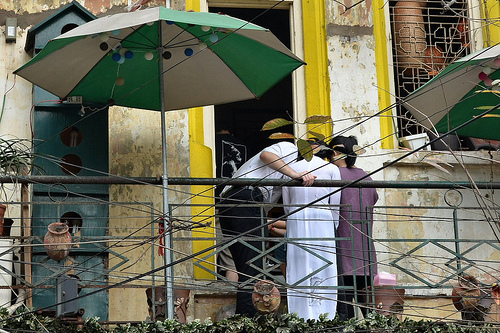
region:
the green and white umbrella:
[10, 5, 306, 114]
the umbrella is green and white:
[11, 7, 309, 115]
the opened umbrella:
[12, 4, 307, 114]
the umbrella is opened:
[10, 6, 307, 114]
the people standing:
[223, 129, 378, 315]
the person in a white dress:
[287, 148, 334, 323]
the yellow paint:
[309, 25, 324, 117]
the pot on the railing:
[46, 217, 67, 261]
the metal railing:
[29, 161, 495, 318]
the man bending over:
[217, 137, 291, 299]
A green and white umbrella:
[67, 26, 230, 91]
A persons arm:
[263, 158, 309, 183]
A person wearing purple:
[341, 168, 380, 234]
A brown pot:
[48, 225, 79, 252]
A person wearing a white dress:
[283, 166, 334, 270]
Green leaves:
[236, 311, 341, 328]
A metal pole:
[153, 112, 174, 194]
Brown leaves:
[263, 120, 307, 142]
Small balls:
[115, 50, 176, 64]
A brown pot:
[233, 277, 283, 311]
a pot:
[232, 281, 310, 325]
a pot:
[231, 264, 283, 316]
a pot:
[234, 250, 299, 330]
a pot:
[238, 280, 295, 307]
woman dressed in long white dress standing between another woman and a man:
[284, 143, 341, 312]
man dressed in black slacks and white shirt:
[216, 136, 324, 313]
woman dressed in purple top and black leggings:
[325, 127, 387, 312]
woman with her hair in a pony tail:
[326, 130, 385, 312]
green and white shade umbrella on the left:
[14, 3, 306, 330]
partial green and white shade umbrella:
[405, 32, 498, 147]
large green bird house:
[14, 12, 122, 310]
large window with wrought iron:
[382, 0, 487, 147]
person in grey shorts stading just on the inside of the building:
[212, 199, 239, 284]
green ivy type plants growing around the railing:
[3, 308, 488, 330]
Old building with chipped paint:
[3, 5, 494, 289]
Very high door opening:
[180, 2, 345, 289]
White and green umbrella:
[21, 7, 311, 281]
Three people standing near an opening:
[202, 111, 387, 326]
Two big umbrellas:
[8, 7, 490, 122]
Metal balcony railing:
[2, 165, 499, 322]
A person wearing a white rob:
[275, 142, 345, 308]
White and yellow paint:
[307, 60, 390, 122]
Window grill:
[381, 5, 481, 150]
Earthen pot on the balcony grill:
[31, 216, 105, 258]